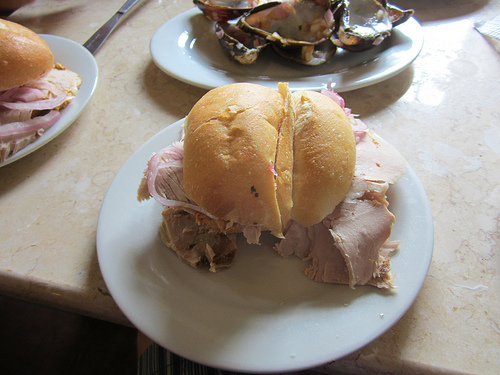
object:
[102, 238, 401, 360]
shadow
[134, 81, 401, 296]
meat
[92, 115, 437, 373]
plate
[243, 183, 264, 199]
spot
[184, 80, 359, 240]
bread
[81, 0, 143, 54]
utensil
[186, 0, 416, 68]
food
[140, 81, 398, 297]
food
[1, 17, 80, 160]
food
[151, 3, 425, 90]
plate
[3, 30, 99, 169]
plate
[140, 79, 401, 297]
sandwich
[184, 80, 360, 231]
sandwich roll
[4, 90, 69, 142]
onion slices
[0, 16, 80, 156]
sandwich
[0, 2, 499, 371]
table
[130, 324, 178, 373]
leg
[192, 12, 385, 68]
shells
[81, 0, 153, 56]
knife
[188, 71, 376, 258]
bun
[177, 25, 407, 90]
shadows